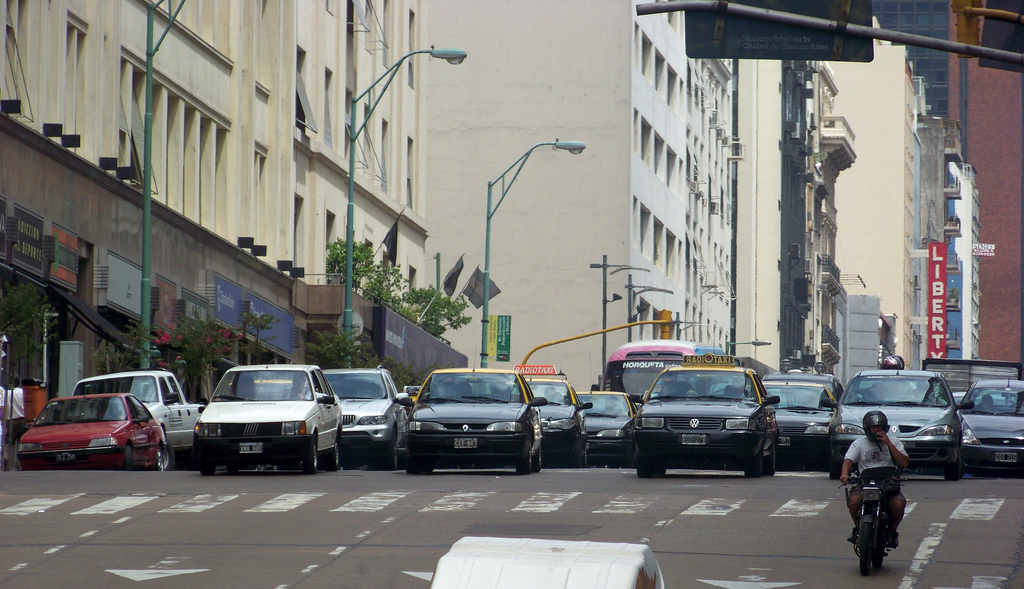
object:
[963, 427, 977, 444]
headlight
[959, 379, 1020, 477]
car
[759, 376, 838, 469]
car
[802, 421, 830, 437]
headlight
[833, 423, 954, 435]
headlight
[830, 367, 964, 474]
car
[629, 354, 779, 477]
car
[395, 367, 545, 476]
car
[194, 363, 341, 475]
car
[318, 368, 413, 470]
car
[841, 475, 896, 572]
motorbike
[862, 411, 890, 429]
helmet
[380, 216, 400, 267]
flag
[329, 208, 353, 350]
pole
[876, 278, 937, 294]
ground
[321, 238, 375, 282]
tree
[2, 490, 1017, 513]
lines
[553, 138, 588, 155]
light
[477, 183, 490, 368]
pole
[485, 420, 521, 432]
headlight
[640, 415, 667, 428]
headlight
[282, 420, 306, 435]
headlight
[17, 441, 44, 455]
headlight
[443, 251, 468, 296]
flag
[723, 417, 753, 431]
headlight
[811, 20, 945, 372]
building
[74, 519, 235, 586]
arrows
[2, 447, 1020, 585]
street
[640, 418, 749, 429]
car headlight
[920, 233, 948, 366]
liberty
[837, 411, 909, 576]
man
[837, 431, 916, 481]
shirt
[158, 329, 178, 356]
flowers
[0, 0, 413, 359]
building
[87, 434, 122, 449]
headlight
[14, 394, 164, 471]
car